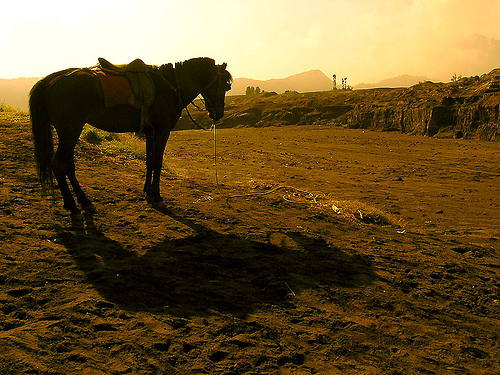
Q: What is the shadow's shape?
A: A horse.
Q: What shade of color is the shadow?
A: Black.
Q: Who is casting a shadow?
A: A horse.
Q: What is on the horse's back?
A: A saddle.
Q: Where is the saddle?
A: On the horse's back.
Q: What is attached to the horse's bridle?
A: A rope.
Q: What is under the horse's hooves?
A: Dirt.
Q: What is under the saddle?
A: A blanket.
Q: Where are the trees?
A: On the hill.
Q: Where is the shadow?
A: On the ground.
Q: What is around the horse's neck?
A: Reins.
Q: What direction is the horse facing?
A: Right.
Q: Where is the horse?
A: In a field.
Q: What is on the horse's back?
A: Saddle.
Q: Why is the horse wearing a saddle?
A: So someone could ride it.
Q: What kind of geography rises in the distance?
A: Hills.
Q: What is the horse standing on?
A: Dirt field.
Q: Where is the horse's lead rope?
A: Hanging down to the ground.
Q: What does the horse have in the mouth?
A: Bit.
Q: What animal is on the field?
A: Horse.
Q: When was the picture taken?
A: Daytime.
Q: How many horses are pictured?
A: One.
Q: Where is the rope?
A: From horse to ground.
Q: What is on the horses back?
A: A saddle.